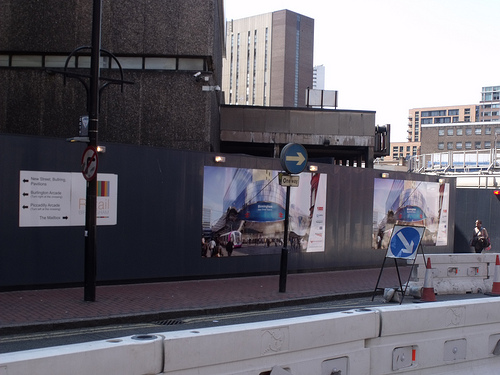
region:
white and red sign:
[81, 149, 98, 179]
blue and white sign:
[281, 142, 308, 174]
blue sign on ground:
[389, 227, 420, 264]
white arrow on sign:
[287, 151, 307, 168]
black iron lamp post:
[86, 0, 104, 299]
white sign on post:
[280, 175, 300, 187]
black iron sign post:
[279, 186, 290, 293]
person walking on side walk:
[471, 220, 491, 256]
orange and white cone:
[422, 258, 437, 301]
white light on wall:
[213, 154, 227, 163]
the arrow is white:
[397, 227, 413, 256]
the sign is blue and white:
[281, 145, 309, 172]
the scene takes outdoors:
[1, 2, 498, 374]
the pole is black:
[91, 2, 99, 302]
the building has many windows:
[389, 88, 496, 157]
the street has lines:
[0, 296, 391, 345]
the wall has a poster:
[203, 172, 328, 259]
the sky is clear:
[308, 0, 499, 140]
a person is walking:
[468, 218, 489, 248]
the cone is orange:
[417, 253, 435, 303]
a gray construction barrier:
[0, 134, 499, 291]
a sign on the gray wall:
[18, 170, 117, 226]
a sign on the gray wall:
[200, 164, 327, 258]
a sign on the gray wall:
[370, 177, 450, 249]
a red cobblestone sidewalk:
[0, 264, 412, 324]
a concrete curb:
[0, 285, 399, 335]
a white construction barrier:
[0, 296, 499, 373]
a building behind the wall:
[0, 0, 390, 169]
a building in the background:
[221, 8, 313, 108]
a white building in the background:
[311, 63, 324, 108]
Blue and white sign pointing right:
[283, 140, 305, 171]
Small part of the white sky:
[386, 28, 404, 45]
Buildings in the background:
[413, 105, 499, 161]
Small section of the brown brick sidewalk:
[133, 284, 199, 310]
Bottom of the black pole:
[86, 249, 96, 296]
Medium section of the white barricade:
[392, 313, 487, 365]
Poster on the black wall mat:
[203, 167, 322, 259]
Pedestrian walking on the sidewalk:
[470, 220, 490, 252]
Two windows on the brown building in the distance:
[451, 125, 475, 136]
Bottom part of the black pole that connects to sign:
[280, 244, 291, 294]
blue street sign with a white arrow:
[276, 141, 308, 293]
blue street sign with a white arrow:
[370, 225, 425, 303]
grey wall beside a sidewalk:
[5, 134, 498, 286]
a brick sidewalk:
[0, 264, 412, 328]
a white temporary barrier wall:
[0, 297, 499, 372]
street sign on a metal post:
[80, 147, 98, 180]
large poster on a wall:
[200, 166, 327, 258]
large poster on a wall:
[372, 176, 448, 246]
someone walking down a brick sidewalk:
[470, 219, 491, 254]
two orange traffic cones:
[420, 254, 499, 303]